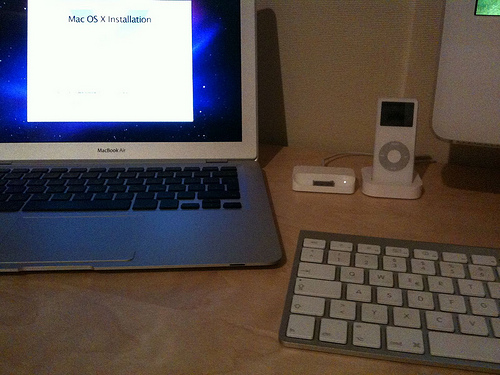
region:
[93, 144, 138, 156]
"macbook air" logo on the laptop.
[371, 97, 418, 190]
ipod nano sitting on the desk.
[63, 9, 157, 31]
memo displayed on the computer screen, about what is going on.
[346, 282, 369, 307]
the "a" key on the keyboard.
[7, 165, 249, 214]
the keyboard on the laptop.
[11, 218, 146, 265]
the mousepad on the laptop.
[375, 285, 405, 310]
the "s" key on the keyboard.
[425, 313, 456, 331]
the "c" key on the keyboard.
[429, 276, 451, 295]
the "e" key on the keyboard.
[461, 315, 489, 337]
the "v" key on the keyboard.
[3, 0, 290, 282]
a laptop is open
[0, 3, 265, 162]
the screen of laptop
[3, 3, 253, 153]
the screen of laptop is white and blue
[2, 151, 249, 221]
the keys of laptop are black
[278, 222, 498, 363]
the keys of laptop are white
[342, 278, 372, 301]
key with letter A on keyboard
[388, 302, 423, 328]
key with letter X on keyboard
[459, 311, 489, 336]
key with letter V on keyboard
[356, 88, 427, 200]
a white iPod on a charger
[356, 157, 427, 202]
charger of iPod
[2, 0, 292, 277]
a laptop over a table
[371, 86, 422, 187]
a white iPod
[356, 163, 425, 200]
a white iPod charger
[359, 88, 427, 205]
iPod on a charger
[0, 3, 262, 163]
screen of laptop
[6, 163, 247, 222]
keys of laptop are black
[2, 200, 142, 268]
touchpad of laptop is gray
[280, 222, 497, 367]
white keys of keyboard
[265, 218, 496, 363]
keys on a gray surface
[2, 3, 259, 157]
a white sheet on screen of laptop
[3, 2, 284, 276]
inside of open laptop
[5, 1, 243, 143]
image on laptop screen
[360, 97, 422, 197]
white ipod on stand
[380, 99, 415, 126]
black screen on ipod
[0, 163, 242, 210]
black buttons on keyboard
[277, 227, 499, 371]
white buttons on keyboard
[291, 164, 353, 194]
small glowing light on electronics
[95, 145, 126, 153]
name of computer maker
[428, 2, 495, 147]
corner of white monitor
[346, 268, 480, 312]
letters on white buttons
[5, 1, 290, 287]
Macbook Air on a desk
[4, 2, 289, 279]
Opened gray Macbook Air on a desk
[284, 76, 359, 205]
charger stand on a desk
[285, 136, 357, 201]
white charger stand on a desk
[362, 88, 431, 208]
white device charging in a stand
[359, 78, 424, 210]
device charging in a charger stand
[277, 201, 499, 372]
part of a computer keyboard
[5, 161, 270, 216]
part of a Macbook Air keyboard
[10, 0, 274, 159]
part of a Macbook Air laptop screen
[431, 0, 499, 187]
corner of an iMac screen